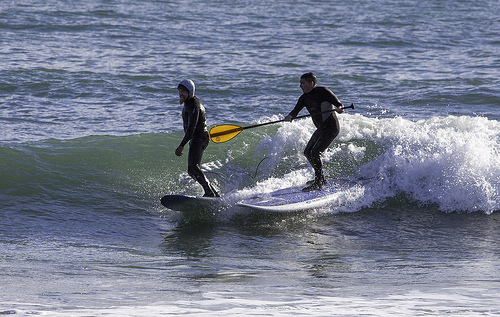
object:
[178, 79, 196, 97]
helmet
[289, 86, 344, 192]
watersuit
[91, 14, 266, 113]
ocean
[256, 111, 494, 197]
wave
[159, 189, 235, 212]
board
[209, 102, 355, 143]
paddle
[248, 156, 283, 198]
cord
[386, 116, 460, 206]
water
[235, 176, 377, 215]
surfboard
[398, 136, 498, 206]
foam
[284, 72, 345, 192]
people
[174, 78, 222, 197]
man